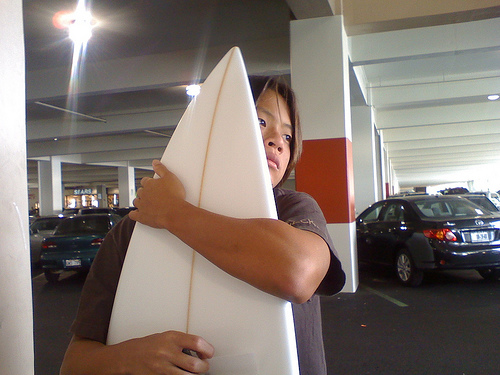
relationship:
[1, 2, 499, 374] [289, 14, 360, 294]
building has a pillar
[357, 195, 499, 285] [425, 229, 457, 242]
car has a light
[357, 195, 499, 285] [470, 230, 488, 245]
car has a number plate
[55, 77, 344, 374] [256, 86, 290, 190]
person has a face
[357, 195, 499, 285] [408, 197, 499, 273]
car has a back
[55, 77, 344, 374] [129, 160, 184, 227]
person has a hand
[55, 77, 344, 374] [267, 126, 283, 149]
person has a nose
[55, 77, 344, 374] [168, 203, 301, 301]
person has a forearm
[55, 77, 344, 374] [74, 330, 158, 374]
person has a forearm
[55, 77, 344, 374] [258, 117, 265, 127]
person has an eye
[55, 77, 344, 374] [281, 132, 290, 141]
person has an right eye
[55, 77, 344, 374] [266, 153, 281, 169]
person has a mouth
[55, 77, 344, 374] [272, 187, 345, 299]
person has a shirt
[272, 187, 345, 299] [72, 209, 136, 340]
shirt has a sleeve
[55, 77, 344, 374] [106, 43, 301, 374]
person has a surfboard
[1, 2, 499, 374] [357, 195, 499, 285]
building has car